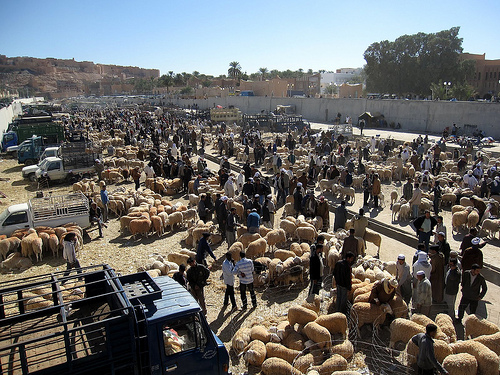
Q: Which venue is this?
A: This is a market.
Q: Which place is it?
A: It is a market.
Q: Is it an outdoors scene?
A: Yes, it is outdoors.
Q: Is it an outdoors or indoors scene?
A: It is outdoors.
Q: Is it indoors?
A: No, it is outdoors.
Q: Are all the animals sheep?
A: Yes, all the animals are sheep.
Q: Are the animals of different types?
A: No, all the animals are sheep.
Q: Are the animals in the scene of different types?
A: No, all the animals are sheep.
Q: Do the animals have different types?
A: No, all the animals are sheep.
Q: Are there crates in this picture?
A: No, there are no crates.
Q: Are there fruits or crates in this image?
A: No, there are no crates or fruits.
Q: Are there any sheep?
A: Yes, there is a sheep.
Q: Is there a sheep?
A: Yes, there is a sheep.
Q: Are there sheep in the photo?
A: Yes, there is a sheep.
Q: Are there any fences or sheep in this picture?
A: Yes, there is a sheep.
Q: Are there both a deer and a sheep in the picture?
A: No, there is a sheep but no deer.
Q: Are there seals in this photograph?
A: No, there are no seals.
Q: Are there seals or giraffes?
A: No, there are no seals or giraffes.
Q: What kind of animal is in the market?
A: The animal is a sheep.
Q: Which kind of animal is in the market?
A: The animal is a sheep.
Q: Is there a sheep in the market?
A: Yes, there is a sheep in the market.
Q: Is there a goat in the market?
A: No, there is a sheep in the market.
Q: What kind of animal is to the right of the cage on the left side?
A: The animal is a sheep.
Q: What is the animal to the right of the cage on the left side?
A: The animal is a sheep.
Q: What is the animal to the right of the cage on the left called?
A: The animal is a sheep.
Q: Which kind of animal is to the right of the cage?
A: The animal is a sheep.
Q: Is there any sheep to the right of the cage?
A: Yes, there is a sheep to the right of the cage.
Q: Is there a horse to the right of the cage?
A: No, there is a sheep to the right of the cage.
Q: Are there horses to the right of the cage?
A: No, there is a sheep to the right of the cage.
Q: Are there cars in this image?
A: No, there are no cars.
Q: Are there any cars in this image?
A: No, there are no cars.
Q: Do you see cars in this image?
A: No, there are no cars.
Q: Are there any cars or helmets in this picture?
A: No, there are no cars or helmets.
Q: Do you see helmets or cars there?
A: No, there are no cars or helmets.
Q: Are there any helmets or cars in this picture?
A: No, there are no cars or helmets.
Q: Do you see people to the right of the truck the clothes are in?
A: Yes, there is a person to the right of the truck.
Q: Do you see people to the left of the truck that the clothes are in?
A: No, the person is to the right of the truck.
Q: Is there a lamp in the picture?
A: No, there are no lamps.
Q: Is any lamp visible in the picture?
A: No, there are no lamps.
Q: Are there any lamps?
A: No, there are no lamps.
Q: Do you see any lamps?
A: No, there are no lamps.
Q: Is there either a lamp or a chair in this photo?
A: No, there are no lamps or chairs.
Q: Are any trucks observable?
A: Yes, there is a truck.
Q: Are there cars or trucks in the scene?
A: Yes, there is a truck.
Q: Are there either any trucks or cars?
A: Yes, there is a truck.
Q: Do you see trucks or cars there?
A: Yes, there is a truck.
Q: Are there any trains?
A: No, there are no trains.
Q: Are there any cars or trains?
A: No, there are no trains or cars.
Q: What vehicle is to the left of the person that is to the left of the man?
A: The vehicle is a truck.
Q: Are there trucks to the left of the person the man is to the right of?
A: Yes, there is a truck to the left of the person.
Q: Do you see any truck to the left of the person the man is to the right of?
A: Yes, there is a truck to the left of the person.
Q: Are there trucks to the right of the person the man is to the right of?
A: No, the truck is to the left of the person.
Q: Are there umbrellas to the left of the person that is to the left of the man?
A: No, there is a truck to the left of the person.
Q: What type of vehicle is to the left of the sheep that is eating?
A: The vehicle is a truck.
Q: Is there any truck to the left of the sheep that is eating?
A: Yes, there is a truck to the left of the sheep.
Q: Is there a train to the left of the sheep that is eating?
A: No, there is a truck to the left of the sheep.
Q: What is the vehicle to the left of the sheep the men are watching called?
A: The vehicle is a truck.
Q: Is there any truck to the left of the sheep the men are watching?
A: Yes, there is a truck to the left of the sheep.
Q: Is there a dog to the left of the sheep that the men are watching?
A: No, there is a truck to the left of the sheep.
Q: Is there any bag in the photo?
A: No, there are no bags.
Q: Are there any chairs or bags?
A: No, there are no bags or chairs.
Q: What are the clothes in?
A: The clothes are in the truck.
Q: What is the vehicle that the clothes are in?
A: The vehicle is a truck.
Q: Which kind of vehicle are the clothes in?
A: The clothes are in the truck.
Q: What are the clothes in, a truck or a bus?
A: The clothes are in a truck.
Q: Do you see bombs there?
A: No, there are no bombs.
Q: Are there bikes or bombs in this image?
A: No, there are no bombs or bikes.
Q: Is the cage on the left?
A: Yes, the cage is on the left of the image.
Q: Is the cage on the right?
A: No, the cage is on the left of the image.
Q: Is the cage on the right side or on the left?
A: The cage is on the left of the image.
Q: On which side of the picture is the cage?
A: The cage is on the left of the image.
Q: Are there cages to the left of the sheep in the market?
A: Yes, there is a cage to the left of the sheep.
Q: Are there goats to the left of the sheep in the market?
A: No, there is a cage to the left of the sheep.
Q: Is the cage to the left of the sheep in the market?
A: Yes, the cage is to the left of the sheep.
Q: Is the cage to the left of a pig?
A: No, the cage is to the left of the sheep.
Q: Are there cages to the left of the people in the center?
A: Yes, there is a cage to the left of the people.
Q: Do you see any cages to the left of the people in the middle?
A: Yes, there is a cage to the left of the people.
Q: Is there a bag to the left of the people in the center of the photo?
A: No, there is a cage to the left of the people.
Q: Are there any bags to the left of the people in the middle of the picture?
A: No, there is a cage to the left of the people.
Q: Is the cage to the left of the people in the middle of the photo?
A: Yes, the cage is to the left of the people.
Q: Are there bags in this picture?
A: No, there are no bags.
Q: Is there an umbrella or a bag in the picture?
A: No, there are no bags or umbrellas.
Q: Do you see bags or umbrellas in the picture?
A: No, there are no bags or umbrellas.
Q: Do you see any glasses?
A: No, there are no glasses.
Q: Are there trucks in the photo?
A: Yes, there is a truck.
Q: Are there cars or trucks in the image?
A: Yes, there is a truck.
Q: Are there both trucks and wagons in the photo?
A: No, there is a truck but no wagons.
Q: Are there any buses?
A: No, there are no buses.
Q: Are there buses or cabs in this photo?
A: No, there are no buses or cabs.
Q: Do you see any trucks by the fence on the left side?
A: Yes, there is a truck by the fence.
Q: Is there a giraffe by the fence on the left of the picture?
A: No, there is a truck by the fence.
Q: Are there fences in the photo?
A: Yes, there is a fence.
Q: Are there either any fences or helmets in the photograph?
A: Yes, there is a fence.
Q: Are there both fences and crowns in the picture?
A: No, there is a fence but no crowns.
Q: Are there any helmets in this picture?
A: No, there are no helmets.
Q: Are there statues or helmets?
A: No, there are no helmets or statues.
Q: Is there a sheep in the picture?
A: Yes, there is a sheep.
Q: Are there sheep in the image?
A: Yes, there is a sheep.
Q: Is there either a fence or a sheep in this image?
A: Yes, there is a sheep.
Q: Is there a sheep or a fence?
A: Yes, there is a sheep.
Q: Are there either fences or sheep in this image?
A: Yes, there is a sheep.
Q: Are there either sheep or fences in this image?
A: Yes, there is a sheep.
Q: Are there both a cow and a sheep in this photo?
A: No, there is a sheep but no cows.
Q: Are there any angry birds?
A: No, there are no angry birds.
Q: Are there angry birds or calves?
A: No, there are no angry birds or calves.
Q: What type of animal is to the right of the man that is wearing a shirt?
A: The animal is a sheep.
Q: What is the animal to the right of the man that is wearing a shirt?
A: The animal is a sheep.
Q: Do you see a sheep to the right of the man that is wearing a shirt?
A: Yes, there is a sheep to the right of the man.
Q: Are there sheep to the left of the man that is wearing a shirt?
A: No, the sheep is to the right of the man.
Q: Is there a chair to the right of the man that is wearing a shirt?
A: No, there is a sheep to the right of the man.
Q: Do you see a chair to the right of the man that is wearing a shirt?
A: No, there is a sheep to the right of the man.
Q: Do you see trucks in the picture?
A: Yes, there is a truck.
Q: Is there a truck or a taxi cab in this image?
A: Yes, there is a truck.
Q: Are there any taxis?
A: No, there are no taxis.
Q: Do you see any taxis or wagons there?
A: No, there are no taxis or wagons.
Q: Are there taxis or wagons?
A: No, there are no taxis or wagons.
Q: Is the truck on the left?
A: Yes, the truck is on the left of the image.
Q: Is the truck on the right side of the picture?
A: No, the truck is on the left of the image.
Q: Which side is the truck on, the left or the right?
A: The truck is on the left of the image.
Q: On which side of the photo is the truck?
A: The truck is on the left of the image.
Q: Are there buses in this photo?
A: No, there are no buses.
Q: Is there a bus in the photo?
A: No, there are no buses.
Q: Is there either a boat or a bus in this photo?
A: No, there are no buses or boats.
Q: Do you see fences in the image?
A: Yes, there is a fence.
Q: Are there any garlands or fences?
A: Yes, there is a fence.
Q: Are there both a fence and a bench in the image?
A: No, there is a fence but no benches.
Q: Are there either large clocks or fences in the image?
A: Yes, there is a large fence.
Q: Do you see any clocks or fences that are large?
A: Yes, the fence is large.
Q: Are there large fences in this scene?
A: Yes, there is a large fence.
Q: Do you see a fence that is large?
A: Yes, there is a large fence.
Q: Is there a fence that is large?
A: Yes, there is a fence that is large.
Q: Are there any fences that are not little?
A: Yes, there is a large fence.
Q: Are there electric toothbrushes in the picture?
A: No, there are no electric toothbrushes.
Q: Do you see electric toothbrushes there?
A: No, there are no electric toothbrushes.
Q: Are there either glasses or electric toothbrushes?
A: No, there are no electric toothbrushes or glasses.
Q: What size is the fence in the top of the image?
A: The fence is large.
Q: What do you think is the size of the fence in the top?
A: The fence is large.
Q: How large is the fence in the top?
A: The fence is large.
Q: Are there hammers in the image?
A: No, there are no hammers.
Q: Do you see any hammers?
A: No, there are no hammers.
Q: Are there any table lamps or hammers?
A: No, there are no hammers or table lamps.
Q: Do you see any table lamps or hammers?
A: No, there are no hammers or table lamps.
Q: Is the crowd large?
A: Yes, the crowd is large.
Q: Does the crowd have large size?
A: Yes, the crowd is large.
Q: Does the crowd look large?
A: Yes, the crowd is large.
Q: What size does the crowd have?
A: The crowd has large size.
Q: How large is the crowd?
A: The crowd is large.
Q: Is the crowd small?
A: No, the crowd is large.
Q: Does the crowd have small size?
A: No, the crowd is large.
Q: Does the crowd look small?
A: No, the crowd is large.